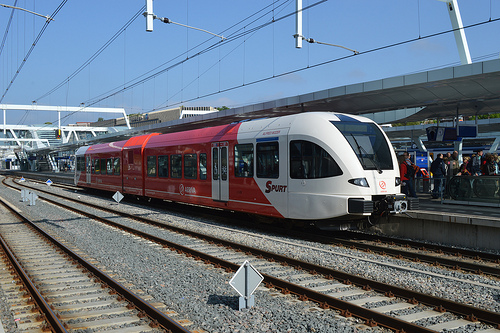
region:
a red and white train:
[72, 108, 407, 218]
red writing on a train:
[265, 178, 288, 197]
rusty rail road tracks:
[10, 203, 157, 321]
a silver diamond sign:
[229, 260, 264, 315]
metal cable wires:
[204, 11, 490, 106]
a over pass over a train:
[1, 103, 123, 143]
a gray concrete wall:
[399, 208, 497, 259]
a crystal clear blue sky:
[12, 1, 491, 62]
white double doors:
[205, 147, 236, 210]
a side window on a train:
[287, 136, 348, 183]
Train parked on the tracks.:
[51, 84, 432, 245]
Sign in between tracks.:
[225, 260, 263, 313]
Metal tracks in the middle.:
[52, 182, 244, 279]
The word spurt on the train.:
[264, 178, 288, 197]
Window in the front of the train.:
[333, 118, 405, 175]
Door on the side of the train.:
[208, 145, 235, 202]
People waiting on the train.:
[411, 150, 494, 207]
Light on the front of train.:
[352, 175, 369, 187]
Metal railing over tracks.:
[6, 100, 132, 132]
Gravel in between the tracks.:
[56, 219, 168, 271]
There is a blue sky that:
[403, 14, 409, 49]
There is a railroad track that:
[308, 215, 361, 300]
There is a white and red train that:
[208, 137, 262, 205]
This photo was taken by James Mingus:
[111, 55, 371, 329]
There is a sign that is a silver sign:
[228, 254, 263, 310]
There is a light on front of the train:
[354, 168, 367, 193]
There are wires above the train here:
[93, 40, 139, 113]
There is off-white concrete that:
[153, 104, 165, 123]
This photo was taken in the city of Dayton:
[116, 51, 360, 329]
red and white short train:
[37, 98, 482, 262]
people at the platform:
[381, 129, 498, 214]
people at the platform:
[404, 146, 496, 199]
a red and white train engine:
[149, 107, 408, 232]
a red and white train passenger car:
[72, 130, 152, 197]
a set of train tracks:
[308, 225, 498, 278]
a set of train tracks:
[1, 168, 498, 331]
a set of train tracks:
[0, 197, 190, 332]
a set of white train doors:
[211, 143, 228, 199]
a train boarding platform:
[401, 189, 498, 222]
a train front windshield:
[330, 117, 393, 170]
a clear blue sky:
[1, 0, 498, 127]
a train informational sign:
[227, 258, 264, 310]